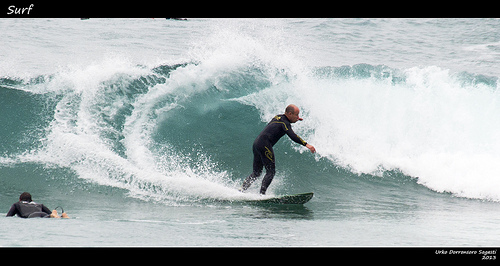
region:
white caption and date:
[433, 246, 498, 262]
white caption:
[5, 2, 40, 17]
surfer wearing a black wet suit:
[6, 189, 73, 221]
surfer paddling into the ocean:
[5, 190, 73, 222]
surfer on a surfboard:
[200, 99, 318, 205]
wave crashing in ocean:
[2, 63, 499, 208]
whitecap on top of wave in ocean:
[31, 27, 308, 92]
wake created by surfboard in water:
[39, 60, 276, 211]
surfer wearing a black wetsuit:
[235, 104, 316, 198]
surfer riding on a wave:
[198, 103, 319, 208]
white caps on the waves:
[310, 85, 498, 186]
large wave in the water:
[1, 72, 240, 202]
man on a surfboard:
[231, 99, 313, 213]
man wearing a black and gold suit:
[252, 108, 280, 186]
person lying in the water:
[4, 184, 71, 229]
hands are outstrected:
[301, 114, 320, 169]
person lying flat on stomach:
[16, 192, 74, 231]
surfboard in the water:
[203, 182, 330, 228]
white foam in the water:
[0, 27, 499, 71]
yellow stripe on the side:
[258, 139, 280, 170]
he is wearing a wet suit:
[185, 67, 378, 218]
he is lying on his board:
[5, 180, 75, 236]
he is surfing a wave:
[195, 75, 375, 260]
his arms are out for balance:
[206, 81, 376, 213]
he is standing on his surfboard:
[200, 90, 390, 240]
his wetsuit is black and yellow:
[235, 80, 340, 215]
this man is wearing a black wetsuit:
[217, 68, 362, 215]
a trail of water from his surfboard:
[51, 81, 245, 201]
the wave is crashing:
[254, 46, 496, 206]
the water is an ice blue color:
[10, 79, 495, 239]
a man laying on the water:
[3, 179, 78, 229]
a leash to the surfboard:
[52, 202, 68, 217]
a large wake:
[76, 101, 240, 214]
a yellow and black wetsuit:
[236, 115, 310, 196]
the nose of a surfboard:
[266, 188, 320, 213]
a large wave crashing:
[311, 51, 496, 211]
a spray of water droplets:
[68, 53, 140, 73]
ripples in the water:
[346, 23, 488, 62]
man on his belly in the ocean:
[7, 188, 78, 228]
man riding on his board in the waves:
[236, 98, 318, 225]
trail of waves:
[34, 42, 240, 201]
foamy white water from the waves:
[15, 40, 498, 209]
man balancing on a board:
[223, 101, 316, 216]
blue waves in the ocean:
[2, 74, 474, 242]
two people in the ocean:
[0, 100, 335, 235]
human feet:
[46, 205, 78, 222]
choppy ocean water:
[6, 20, 496, 245]